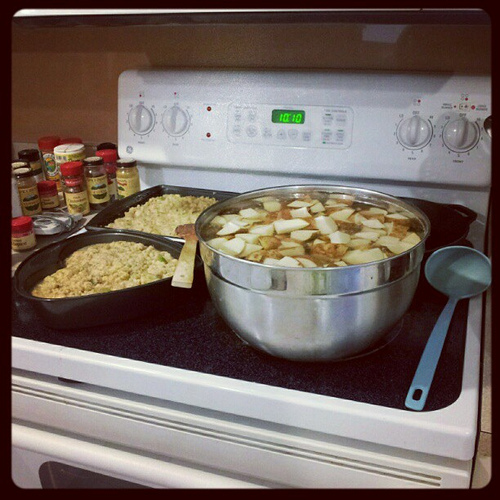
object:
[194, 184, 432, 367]
bowl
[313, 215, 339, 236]
potatoes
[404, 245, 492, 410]
spoon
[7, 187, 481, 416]
stove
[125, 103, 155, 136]
knob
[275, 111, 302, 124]
letters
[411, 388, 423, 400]
hole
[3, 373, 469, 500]
lines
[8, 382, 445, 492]
door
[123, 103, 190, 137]
knobs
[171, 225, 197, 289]
spoon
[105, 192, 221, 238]
food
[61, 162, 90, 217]
container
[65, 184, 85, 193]
herbs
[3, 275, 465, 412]
surface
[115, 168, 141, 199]
spices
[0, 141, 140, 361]
counter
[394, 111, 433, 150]
knobs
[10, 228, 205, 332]
casserole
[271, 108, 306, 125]
clock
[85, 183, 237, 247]
pan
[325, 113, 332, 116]
button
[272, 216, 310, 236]
potatoes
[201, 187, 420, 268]
water